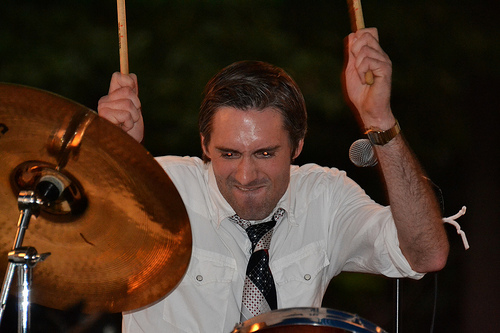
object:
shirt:
[122, 150, 427, 332]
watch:
[359, 117, 402, 150]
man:
[96, 28, 451, 332]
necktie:
[231, 209, 286, 322]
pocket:
[269, 239, 336, 310]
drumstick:
[112, 0, 138, 76]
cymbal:
[0, 79, 195, 316]